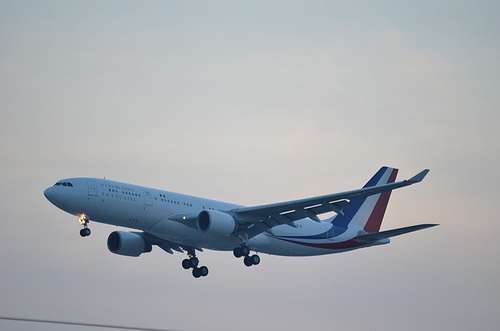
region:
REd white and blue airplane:
[25, 138, 455, 291]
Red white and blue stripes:
[269, 157, 399, 260]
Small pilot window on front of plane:
[52, 179, 79, 186]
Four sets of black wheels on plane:
[176, 234, 262, 303]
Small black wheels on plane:
[80, 221, 92, 241]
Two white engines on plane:
[95, 201, 242, 267]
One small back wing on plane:
[359, 213, 435, 255]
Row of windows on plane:
[97, 178, 241, 220]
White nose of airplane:
[37, 169, 89, 211]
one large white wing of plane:
[197, 160, 439, 238]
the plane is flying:
[28, 129, 432, 274]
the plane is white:
[41, 151, 346, 307]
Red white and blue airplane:
[40, 146, 448, 293]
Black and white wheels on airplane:
[180, 244, 271, 286]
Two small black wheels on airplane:
[76, 221, 98, 242]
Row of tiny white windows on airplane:
[107, 186, 237, 217]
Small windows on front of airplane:
[52, 178, 78, 190]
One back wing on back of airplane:
[327, 153, 397, 228]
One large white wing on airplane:
[214, 171, 429, 237]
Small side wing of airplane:
[359, 218, 453, 249]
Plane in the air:
[38, 160, 443, 279]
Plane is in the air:
[41, 158, 441, 279]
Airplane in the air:
[40, 160, 440, 279]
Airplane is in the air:
[41, 163, 441, 279]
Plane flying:
[40, 160, 443, 281]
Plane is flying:
[38, 160, 450, 280]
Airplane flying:
[36, 155, 449, 280]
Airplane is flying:
[42, 156, 442, 281]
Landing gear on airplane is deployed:
[77, 216, 267, 285]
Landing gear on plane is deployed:
[77, 216, 262, 282]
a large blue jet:
[42, 164, 442, 279]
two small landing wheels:
[76, 227, 91, 239]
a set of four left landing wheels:
[232, 241, 262, 267]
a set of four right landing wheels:
[178, 255, 211, 276]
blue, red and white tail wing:
[315, 161, 397, 231]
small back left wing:
[346, 218, 441, 253]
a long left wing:
[231, 167, 432, 242]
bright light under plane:
[75, 211, 89, 223]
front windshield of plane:
[54, 179, 74, 189]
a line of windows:
[97, 179, 233, 214]